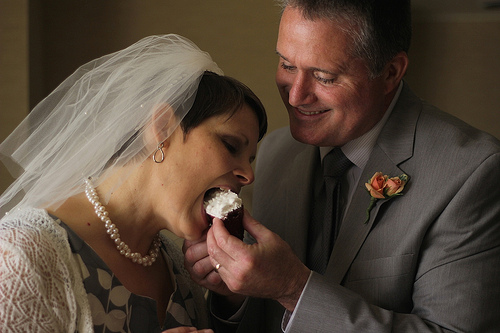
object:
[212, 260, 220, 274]
ring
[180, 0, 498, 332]
man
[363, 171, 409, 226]
flower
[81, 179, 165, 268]
necklace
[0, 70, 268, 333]
woman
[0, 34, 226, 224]
veil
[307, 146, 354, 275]
tie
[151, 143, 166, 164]
earring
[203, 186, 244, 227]
cake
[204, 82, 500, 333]
suit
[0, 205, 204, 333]
sweater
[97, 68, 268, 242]
head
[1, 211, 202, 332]
dress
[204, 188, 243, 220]
frosting